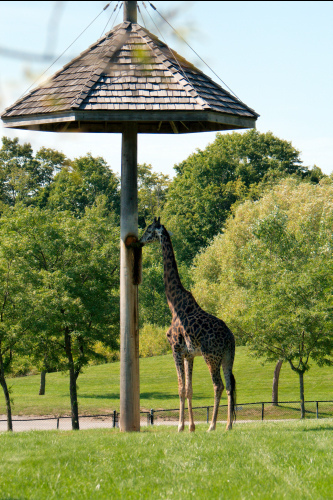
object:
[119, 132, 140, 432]
large gray pole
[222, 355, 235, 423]
back legs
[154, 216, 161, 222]
ears of giraffe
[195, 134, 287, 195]
green trees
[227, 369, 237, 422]
hairy tail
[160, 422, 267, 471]
grass beneath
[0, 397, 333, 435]
small fence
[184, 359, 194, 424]
front legs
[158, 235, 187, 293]
long neck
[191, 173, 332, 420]
near the fence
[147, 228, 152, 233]
left eye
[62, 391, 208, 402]
shadow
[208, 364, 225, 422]
back legs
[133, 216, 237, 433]
giraffe stading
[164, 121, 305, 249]
trees with branches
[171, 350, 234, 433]
leg of the giraffe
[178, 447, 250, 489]
green grass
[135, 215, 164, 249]
head of the giraffe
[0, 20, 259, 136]
giraffe tent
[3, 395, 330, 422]
coated metal fencing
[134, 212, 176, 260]
giraffe eating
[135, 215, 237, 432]
giraffe in the grass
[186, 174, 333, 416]
large tree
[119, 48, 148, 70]
shingle on a roof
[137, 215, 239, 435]
standing in the zoo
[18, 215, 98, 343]
trees with branches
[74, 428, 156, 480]
green color grass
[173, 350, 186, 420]
long legs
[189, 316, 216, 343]
tail with fringes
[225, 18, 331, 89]
blue color sky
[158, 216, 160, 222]
knobbed horn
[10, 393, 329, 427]
fencing near